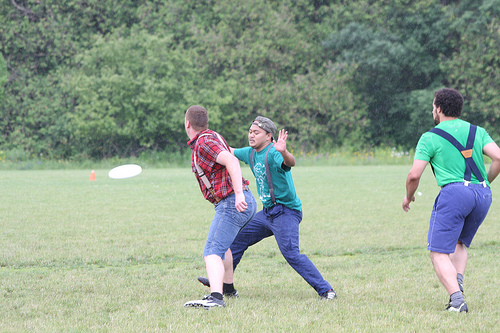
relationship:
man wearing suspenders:
[402, 89, 499, 321] [421, 120, 486, 186]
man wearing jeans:
[196, 110, 342, 304] [225, 200, 332, 300]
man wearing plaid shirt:
[183, 105, 259, 311] [188, 128, 246, 201]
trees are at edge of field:
[0, 0, 498, 163] [1, 158, 497, 327]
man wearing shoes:
[171, 111, 261, 232] [174, 267, 264, 324]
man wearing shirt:
[171, 111, 261, 232] [172, 126, 270, 183]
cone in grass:
[83, 166, 100, 188] [4, 157, 484, 318]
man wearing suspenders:
[402, 89, 499, 321] [421, 117, 496, 187]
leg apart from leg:
[212, 204, 272, 292] [270, 215, 328, 301]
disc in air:
[107, 164, 142, 180] [6, 12, 187, 222]